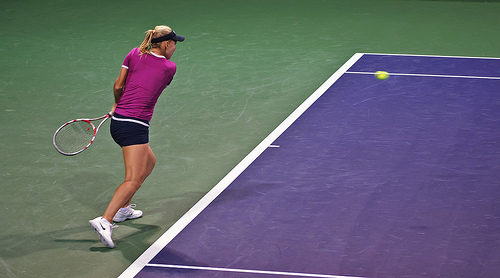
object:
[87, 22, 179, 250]
lady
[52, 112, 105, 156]
racket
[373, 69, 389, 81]
ball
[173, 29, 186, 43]
visor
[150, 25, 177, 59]
head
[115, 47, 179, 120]
shirt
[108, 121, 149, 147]
short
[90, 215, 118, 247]
shoes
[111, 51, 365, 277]
baseline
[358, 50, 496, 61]
sideline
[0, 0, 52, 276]
ground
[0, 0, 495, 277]
area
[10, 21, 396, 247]
playing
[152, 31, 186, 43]
cap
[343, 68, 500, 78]
line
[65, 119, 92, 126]
colors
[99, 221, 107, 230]
one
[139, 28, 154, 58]
pony tail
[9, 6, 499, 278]
court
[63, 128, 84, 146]
netting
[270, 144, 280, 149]
line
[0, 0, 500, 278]
air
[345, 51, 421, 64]
edge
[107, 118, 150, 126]
edge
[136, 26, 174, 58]
hair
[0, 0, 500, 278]
view